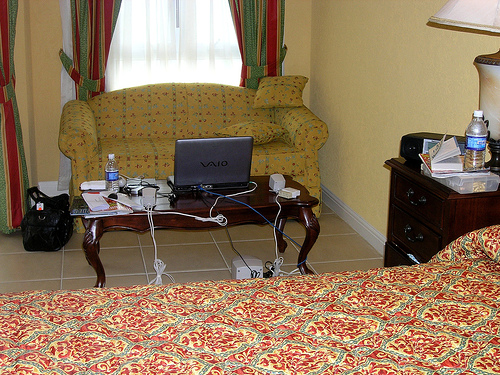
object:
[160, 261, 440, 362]
bed spread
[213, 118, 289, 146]
pillow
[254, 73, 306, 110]
pillow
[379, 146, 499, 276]
night table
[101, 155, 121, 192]
water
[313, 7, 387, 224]
wall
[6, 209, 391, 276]
tile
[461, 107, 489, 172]
bottle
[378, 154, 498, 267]
nightstand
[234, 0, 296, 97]
curtains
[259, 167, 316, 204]
speaker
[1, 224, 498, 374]
spread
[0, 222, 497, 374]
bed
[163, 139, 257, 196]
laptop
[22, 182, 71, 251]
black bag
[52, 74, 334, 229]
sofa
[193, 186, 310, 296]
cord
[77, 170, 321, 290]
coffee table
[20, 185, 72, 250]
bag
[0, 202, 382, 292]
floor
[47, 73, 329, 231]
couch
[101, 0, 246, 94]
window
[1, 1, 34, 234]
curtain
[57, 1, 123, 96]
curtain